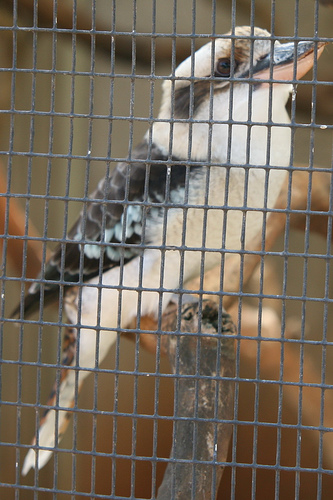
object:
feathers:
[157, 227, 183, 285]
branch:
[0, 158, 52, 290]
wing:
[0, 137, 204, 327]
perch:
[150, 298, 251, 498]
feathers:
[117, 178, 182, 241]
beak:
[254, 41, 326, 85]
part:
[171, 355, 237, 421]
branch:
[205, 160, 332, 311]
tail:
[20, 366, 84, 477]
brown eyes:
[213, 57, 239, 78]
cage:
[0, 0, 332, 498]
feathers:
[91, 235, 126, 340]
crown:
[169, 40, 216, 89]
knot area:
[171, 295, 247, 339]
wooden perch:
[1, 0, 332, 498]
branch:
[225, 298, 333, 468]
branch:
[157, 295, 238, 497]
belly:
[193, 117, 290, 263]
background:
[0, 0, 332, 498]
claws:
[179, 294, 220, 323]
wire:
[46, 52, 90, 83]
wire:
[101, 84, 147, 128]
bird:
[0, 25, 328, 476]